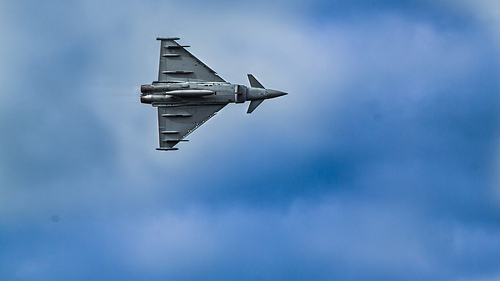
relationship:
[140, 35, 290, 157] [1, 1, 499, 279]
plane in sky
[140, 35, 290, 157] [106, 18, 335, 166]
plane near clouds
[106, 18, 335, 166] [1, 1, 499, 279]
clouds in sky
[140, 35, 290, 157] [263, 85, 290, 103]
plane has tip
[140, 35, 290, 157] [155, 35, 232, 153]
plane has wings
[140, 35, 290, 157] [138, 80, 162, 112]
plane has tail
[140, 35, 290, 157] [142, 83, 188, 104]
plane has engine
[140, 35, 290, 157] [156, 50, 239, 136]
plane has underbelly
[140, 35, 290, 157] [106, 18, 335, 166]
plane flying in clouds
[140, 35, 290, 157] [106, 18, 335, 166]
plane in clouds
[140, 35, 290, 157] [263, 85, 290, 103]
plane as tip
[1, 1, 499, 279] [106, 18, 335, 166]
sky has clouds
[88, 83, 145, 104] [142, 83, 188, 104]
fire from engine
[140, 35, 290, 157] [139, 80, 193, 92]
plane has fuel tank